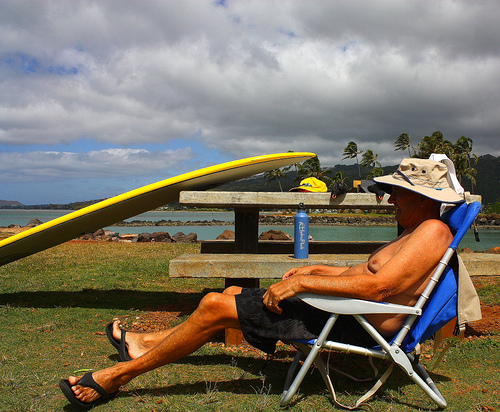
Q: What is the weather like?
A: It is cloudy.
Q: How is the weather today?
A: It is cloudy.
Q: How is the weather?
A: It is cloudy.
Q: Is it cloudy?
A: Yes, it is cloudy.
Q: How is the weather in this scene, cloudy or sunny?
A: It is cloudy.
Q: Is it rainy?
A: No, it is cloudy.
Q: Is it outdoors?
A: Yes, it is outdoors.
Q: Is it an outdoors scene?
A: Yes, it is outdoors.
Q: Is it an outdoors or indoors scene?
A: It is outdoors.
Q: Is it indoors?
A: No, it is outdoors.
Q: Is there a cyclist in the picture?
A: No, there are no cyclists.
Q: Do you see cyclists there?
A: No, there are no cyclists.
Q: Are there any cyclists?
A: No, there are no cyclists.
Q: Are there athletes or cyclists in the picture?
A: No, there are no cyclists or athletes.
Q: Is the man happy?
A: Yes, the man is happy.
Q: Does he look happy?
A: Yes, the man is happy.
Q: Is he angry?
A: No, the man is happy.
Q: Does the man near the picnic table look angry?
A: No, the man is happy.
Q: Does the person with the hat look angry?
A: No, the man is happy.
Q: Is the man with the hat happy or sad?
A: The man is happy.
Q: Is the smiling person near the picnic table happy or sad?
A: The man is happy.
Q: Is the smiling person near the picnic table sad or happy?
A: The man is happy.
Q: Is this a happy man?
A: Yes, this is a happy man.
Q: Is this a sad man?
A: No, this is a happy man.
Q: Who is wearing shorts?
A: The man is wearing shorts.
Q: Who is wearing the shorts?
A: The man is wearing shorts.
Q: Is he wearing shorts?
A: Yes, the man is wearing shorts.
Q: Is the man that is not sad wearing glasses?
A: No, the man is wearing shorts.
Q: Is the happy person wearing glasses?
A: No, the man is wearing shorts.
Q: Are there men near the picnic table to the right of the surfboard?
A: Yes, there is a man near the picnic table.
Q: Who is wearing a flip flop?
A: The man is wearing a flip flop.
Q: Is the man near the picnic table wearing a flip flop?
A: Yes, the man is wearing a flip flop.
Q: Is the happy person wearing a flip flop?
A: Yes, the man is wearing a flip flop.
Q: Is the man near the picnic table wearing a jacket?
A: No, the man is wearing a flip flop.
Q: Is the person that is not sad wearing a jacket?
A: No, the man is wearing a flip flop.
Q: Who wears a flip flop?
A: The man wears a flip flop.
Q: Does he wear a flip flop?
A: Yes, the man wears a flip flop.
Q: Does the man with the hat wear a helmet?
A: No, the man wears a flip flop.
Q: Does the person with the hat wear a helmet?
A: No, the man wears a flip flop.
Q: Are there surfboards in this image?
A: Yes, there is a surfboard.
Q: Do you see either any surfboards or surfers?
A: Yes, there is a surfboard.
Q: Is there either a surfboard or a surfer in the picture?
A: Yes, there is a surfboard.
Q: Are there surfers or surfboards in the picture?
A: Yes, there is a surfboard.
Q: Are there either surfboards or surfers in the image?
A: Yes, there is a surfboard.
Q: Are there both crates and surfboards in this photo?
A: No, there is a surfboard but no crates.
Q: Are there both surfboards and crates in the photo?
A: No, there is a surfboard but no crates.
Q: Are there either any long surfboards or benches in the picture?
A: Yes, there is a long surfboard.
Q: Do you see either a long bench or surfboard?
A: Yes, there is a long surfboard.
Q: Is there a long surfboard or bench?
A: Yes, there is a long surfboard.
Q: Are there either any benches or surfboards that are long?
A: Yes, the surfboard is long.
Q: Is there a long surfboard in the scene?
A: Yes, there is a long surfboard.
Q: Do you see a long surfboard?
A: Yes, there is a long surfboard.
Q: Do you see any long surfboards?
A: Yes, there is a long surfboard.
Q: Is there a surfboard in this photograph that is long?
A: Yes, there is a surfboard that is long.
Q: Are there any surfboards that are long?
A: Yes, there is a surfboard that is long.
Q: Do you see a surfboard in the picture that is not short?
A: Yes, there is a long surfboard.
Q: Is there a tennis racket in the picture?
A: No, there are no rackets.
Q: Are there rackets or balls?
A: No, there are no rackets or balls.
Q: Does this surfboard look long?
A: Yes, the surfboard is long.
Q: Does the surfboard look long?
A: Yes, the surfboard is long.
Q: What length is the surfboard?
A: The surfboard is long.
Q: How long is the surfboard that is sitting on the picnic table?
A: The surfboard is long.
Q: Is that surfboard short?
A: No, the surfboard is long.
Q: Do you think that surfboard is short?
A: No, the surfboard is long.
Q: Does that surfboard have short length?
A: No, the surfboard is long.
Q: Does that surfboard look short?
A: No, the surfboard is long.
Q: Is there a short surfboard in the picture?
A: No, there is a surfboard but it is long.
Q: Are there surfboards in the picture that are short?
A: No, there is a surfboard but it is long.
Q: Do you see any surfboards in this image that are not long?
A: No, there is a surfboard but it is long.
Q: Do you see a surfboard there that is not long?
A: No, there is a surfboard but it is long.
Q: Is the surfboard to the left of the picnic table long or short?
A: The surfboard is long.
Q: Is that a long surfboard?
A: Yes, that is a long surfboard.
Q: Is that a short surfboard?
A: No, that is a long surfboard.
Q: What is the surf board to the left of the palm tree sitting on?
A: The surfboard is sitting on the picnic table.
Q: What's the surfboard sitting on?
A: The surfboard is sitting on the picnic table.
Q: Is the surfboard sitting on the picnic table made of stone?
A: Yes, the surfboard is sitting on the picnic table.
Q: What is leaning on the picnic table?
A: The surfboard is leaning on the picnic table.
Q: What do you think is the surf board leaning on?
A: The surf board is leaning on the picnic table.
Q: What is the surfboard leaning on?
A: The surf board is leaning on the picnic table.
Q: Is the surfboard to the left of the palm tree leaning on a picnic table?
A: Yes, the surfboard is leaning on a picnic table.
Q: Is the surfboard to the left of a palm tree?
A: Yes, the surfboard is to the left of a palm tree.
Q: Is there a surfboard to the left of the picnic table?
A: Yes, there is a surfboard to the left of the picnic table.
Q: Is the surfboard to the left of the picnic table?
A: Yes, the surfboard is to the left of the picnic table.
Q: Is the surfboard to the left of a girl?
A: No, the surfboard is to the left of the picnic table.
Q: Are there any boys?
A: No, there are no boys.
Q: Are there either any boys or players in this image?
A: No, there are no boys or players.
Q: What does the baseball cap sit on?
A: The cap sits on the picnic table.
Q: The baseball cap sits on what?
A: The cap sits on the picnic table.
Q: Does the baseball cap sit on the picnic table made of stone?
A: Yes, the cap sits on the picnic table.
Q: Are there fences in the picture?
A: No, there are no fences.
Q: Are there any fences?
A: No, there are no fences.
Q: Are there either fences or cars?
A: No, there are no fences or cars.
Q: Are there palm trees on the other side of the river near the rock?
A: Yes, there is a palm tree on the other side of the river.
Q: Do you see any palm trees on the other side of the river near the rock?
A: Yes, there is a palm tree on the other side of the river.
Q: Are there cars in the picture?
A: No, there are no cars.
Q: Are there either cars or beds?
A: No, there are no cars or beds.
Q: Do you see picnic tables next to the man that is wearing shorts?
A: Yes, there is a picnic table next to the man.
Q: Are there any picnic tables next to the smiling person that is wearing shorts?
A: Yes, there is a picnic table next to the man.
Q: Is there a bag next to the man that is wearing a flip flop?
A: No, there is a picnic table next to the man.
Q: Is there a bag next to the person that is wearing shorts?
A: No, there is a picnic table next to the man.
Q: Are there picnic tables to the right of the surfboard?
A: Yes, there is a picnic table to the right of the surfboard.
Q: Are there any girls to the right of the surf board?
A: No, there is a picnic table to the right of the surf board.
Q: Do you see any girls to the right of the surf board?
A: No, there is a picnic table to the right of the surf board.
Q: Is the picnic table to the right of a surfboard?
A: Yes, the picnic table is to the right of a surfboard.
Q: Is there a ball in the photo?
A: No, there are no balls.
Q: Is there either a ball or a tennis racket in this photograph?
A: No, there are no balls or rackets.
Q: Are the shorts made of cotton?
A: Yes, the shorts are made of cotton.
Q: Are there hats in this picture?
A: Yes, there is a hat.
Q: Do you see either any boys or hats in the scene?
A: Yes, there is a hat.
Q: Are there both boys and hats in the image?
A: No, there is a hat but no boys.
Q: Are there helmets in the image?
A: No, there are no helmets.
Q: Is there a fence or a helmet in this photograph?
A: No, there are no helmets or fences.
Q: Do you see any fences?
A: No, there are no fences.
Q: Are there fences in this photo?
A: No, there are no fences.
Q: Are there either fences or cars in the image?
A: No, there are no fences or cars.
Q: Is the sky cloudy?
A: Yes, the sky is cloudy.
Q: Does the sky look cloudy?
A: Yes, the sky is cloudy.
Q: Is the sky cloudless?
A: No, the sky is cloudy.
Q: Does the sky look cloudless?
A: No, the sky is cloudy.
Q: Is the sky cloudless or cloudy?
A: The sky is cloudy.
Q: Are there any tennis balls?
A: No, there are no tennis balls.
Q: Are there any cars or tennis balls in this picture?
A: No, there are no tennis balls or cars.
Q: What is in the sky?
A: The clouds are in the sky.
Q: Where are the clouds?
A: The clouds are in the sky.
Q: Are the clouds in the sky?
A: Yes, the clouds are in the sky.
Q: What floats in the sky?
A: The clouds float in the sky.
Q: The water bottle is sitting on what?
A: The water bottle is sitting on the picnic table.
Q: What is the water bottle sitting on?
A: The water bottle is sitting on the picnic table.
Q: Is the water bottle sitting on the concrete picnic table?
A: Yes, the water bottle is sitting on the picnic table.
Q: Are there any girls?
A: No, there are no girls.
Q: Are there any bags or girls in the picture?
A: No, there are no girls or bags.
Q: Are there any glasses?
A: No, there are no glasses.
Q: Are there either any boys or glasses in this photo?
A: No, there are no glasses or boys.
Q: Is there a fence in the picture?
A: No, there are no fences.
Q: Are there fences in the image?
A: No, there are no fences.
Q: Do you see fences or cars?
A: No, there are no fences or cars.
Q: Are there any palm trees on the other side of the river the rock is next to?
A: Yes, there is a palm tree on the other side of the river.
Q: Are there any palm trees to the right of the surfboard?
A: Yes, there is a palm tree to the right of the surfboard.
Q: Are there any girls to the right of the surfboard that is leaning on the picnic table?
A: No, there is a palm tree to the right of the surfboard.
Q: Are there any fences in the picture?
A: No, there are no fences.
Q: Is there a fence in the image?
A: No, there are no fences.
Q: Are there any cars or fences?
A: No, there are no fences or cars.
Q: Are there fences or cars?
A: No, there are no fences or cars.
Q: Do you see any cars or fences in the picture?
A: No, there are no fences or cars.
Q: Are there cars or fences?
A: No, there are no fences or cars.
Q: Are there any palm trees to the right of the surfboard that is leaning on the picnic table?
A: Yes, there is a palm tree to the right of the surfboard.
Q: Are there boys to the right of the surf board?
A: No, there is a palm tree to the right of the surf board.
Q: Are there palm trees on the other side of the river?
A: Yes, there is a palm tree on the other side of the river.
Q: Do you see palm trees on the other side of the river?
A: Yes, there is a palm tree on the other side of the river.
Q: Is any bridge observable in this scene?
A: No, there are no bridges.